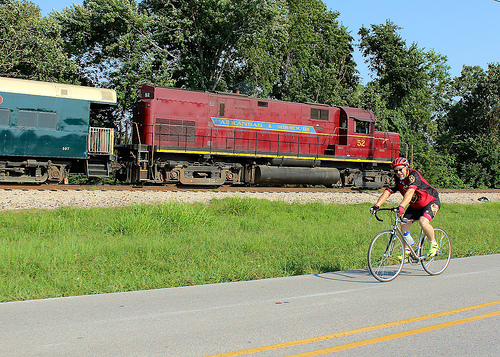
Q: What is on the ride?
A: Bike.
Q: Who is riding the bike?
A: Adult man.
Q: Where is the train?
A: On tracks.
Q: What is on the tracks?
A: Train.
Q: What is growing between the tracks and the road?
A: Grass.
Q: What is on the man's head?
A: Helmet.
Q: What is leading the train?
A: Engine.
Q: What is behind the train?
A: Trees.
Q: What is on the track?
A: A train.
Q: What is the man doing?
A: Riding a bike.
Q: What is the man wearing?
A: A helmet.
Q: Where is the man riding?
A: On the side of the road.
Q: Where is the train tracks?
A: Parallel to the street.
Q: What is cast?
A: Shadow.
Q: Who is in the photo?
A: A biker.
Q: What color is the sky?
A: Blue.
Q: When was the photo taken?
A: Daytime.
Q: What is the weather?
A: Sunny.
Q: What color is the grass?
A: Green.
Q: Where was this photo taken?
A: Near train.